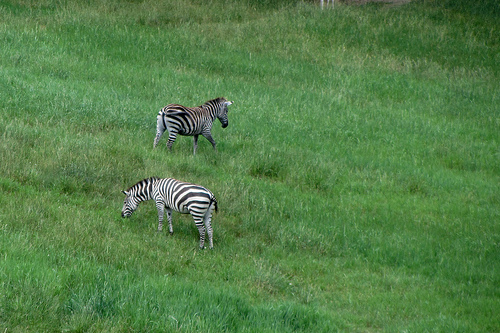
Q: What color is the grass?
A: Green.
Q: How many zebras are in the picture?
A: Two.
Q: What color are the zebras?
A: Black and white.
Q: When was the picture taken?
A: Day time.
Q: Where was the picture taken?
A: A nature reserve.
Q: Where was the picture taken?
A: In the safari.